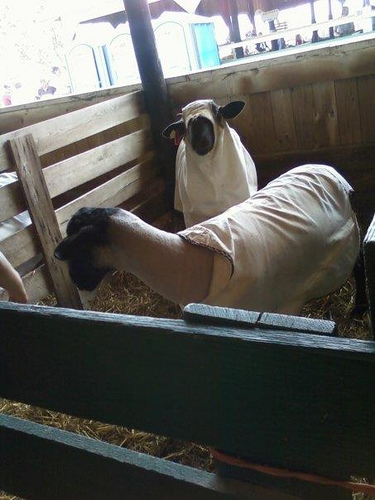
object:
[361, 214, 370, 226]
ground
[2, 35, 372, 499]
enclosure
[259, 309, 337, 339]
vertical plank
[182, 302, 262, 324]
vertical plank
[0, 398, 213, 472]
straw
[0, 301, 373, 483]
planks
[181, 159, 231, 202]
cloth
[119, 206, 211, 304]
neck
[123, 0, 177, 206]
pole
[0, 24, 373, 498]
pen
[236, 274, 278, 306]
cloth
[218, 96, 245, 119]
ear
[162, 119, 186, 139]
ear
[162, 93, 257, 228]
sheep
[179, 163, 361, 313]
covering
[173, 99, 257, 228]
covering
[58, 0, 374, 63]
building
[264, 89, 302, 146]
plank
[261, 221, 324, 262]
cloth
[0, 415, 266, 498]
plank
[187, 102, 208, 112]
cloth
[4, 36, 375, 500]
fences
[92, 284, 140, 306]
hay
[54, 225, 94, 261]
ear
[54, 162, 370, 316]
body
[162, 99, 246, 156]
head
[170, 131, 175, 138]
tag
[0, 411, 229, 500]
light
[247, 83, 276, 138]
plank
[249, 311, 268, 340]
joint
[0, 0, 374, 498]
area